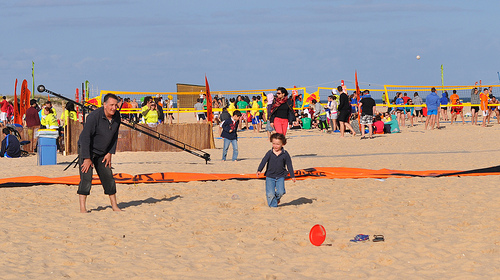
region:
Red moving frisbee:
[304, 222, 329, 248]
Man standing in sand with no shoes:
[72, 91, 124, 215]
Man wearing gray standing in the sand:
[75, 91, 125, 215]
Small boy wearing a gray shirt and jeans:
[254, 132, 297, 207]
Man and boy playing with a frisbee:
[73, 91, 329, 246]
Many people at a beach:
[0, 56, 495, 278]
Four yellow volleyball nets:
[83, 82, 498, 129]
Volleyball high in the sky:
[412, 50, 424, 62]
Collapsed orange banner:
[0, 165, 499, 181]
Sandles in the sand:
[343, 230, 391, 245]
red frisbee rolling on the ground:
[308, 223, 325, 245]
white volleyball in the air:
[415, 55, 421, 60]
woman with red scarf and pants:
[268, 85, 289, 137]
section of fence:
[1, 118, 214, 150]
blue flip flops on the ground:
[349, 233, 384, 242]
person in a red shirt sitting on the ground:
[373, 115, 384, 135]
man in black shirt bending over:
[77, 93, 121, 212]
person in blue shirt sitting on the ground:
[2, 128, 19, 157]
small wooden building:
[174, 81, 206, 110]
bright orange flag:
[203, 75, 215, 122]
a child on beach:
[256, 133, 301, 207]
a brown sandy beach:
[0, 113, 499, 278]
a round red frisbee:
[307, 221, 327, 246]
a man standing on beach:
[74, 92, 129, 214]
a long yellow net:
[382, 83, 498, 108]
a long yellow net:
[316, 84, 476, 109]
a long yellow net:
[209, 87, 309, 111]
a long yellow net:
[99, 87, 264, 117]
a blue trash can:
[30, 129, 60, 166]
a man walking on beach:
[332, 86, 357, 138]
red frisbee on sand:
[300, 214, 335, 263]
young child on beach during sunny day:
[257, 134, 317, 214]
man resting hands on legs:
[62, 87, 134, 215]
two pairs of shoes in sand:
[343, 225, 398, 266]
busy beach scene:
[235, 64, 410, 149]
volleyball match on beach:
[381, 71, 498, 140]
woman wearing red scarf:
[267, 83, 296, 142]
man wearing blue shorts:
[422, 89, 444, 134]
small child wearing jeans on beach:
[257, 137, 293, 208]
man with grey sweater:
[80, 99, 126, 216]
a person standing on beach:
[424, 85, 439, 129]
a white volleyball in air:
[414, 52, 421, 60]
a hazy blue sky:
[2, 2, 499, 103]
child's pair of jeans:
[263, 175, 284, 206]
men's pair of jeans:
[219, 138, 237, 159]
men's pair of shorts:
[358, 112, 374, 125]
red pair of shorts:
[270, 117, 287, 137]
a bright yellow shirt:
[142, 107, 157, 124]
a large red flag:
[11, 75, 18, 122]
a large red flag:
[19, 78, 29, 120]